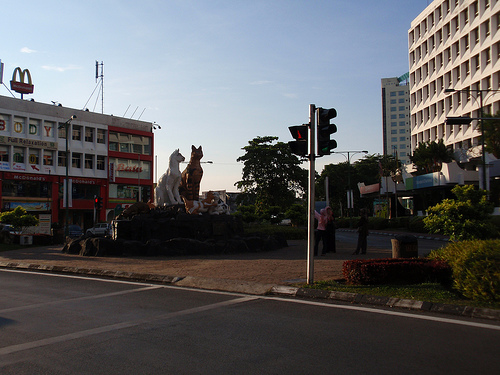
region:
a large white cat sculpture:
[157, 150, 183, 203]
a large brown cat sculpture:
[178, 145, 203, 200]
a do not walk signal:
[288, 123, 308, 160]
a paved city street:
[0, 269, 498, 374]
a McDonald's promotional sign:
[9, 65, 34, 95]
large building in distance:
[380, 71, 410, 164]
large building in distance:
[406, 0, 498, 212]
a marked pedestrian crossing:
[0, 282, 256, 358]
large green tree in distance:
[237, 135, 308, 218]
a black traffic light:
[285, 94, 352, 181]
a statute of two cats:
[147, 131, 237, 233]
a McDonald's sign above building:
[8, 62, 43, 104]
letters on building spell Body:
[1, 114, 58, 148]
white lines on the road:
[5, 259, 499, 369]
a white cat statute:
[142, 142, 195, 227]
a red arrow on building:
[26, 157, 51, 183]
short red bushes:
[332, 247, 474, 301]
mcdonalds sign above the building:
[9, 65, 36, 98]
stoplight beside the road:
[286, 96, 341, 298]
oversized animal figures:
[157, 140, 210, 210]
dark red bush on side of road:
[340, 254, 453, 290]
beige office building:
[397, 0, 497, 177]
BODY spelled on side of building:
[1, 115, 56, 139]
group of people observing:
[305, 198, 375, 260]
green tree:
[1, 199, 37, 249]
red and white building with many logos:
[2, 93, 158, 245]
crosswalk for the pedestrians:
[1, 294, 209, 328]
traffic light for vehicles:
[318, 105, 340, 156]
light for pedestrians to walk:
[286, 121, 309, 158]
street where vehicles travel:
[11, 286, 260, 372]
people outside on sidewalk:
[298, 200, 373, 245]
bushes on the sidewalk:
[336, 228, 495, 314]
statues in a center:
[133, 147, 228, 214]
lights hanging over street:
[321, 140, 376, 160]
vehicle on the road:
[81, 218, 116, 236]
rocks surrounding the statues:
[79, 225, 294, 267]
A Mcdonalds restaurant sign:
[7, 62, 36, 96]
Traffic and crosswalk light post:
[281, 98, 341, 290]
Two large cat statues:
[152, 140, 214, 217]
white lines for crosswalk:
[1, 283, 261, 357]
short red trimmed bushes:
[328, 249, 454, 291]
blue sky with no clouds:
[134, 18, 349, 85]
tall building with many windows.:
[403, 8, 499, 194]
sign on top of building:
[91, 56, 113, 114]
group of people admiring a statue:
[312, 204, 382, 255]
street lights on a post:
[443, 80, 498, 197]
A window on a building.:
[437, 96, 447, 121]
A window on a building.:
[437, 53, 444, 69]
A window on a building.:
[446, 46, 454, 61]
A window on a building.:
[451, 38, 458, 58]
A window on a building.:
[457, 35, 468, 55]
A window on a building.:
[469, 27, 476, 51]